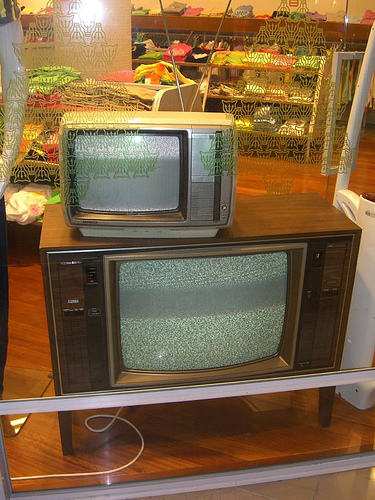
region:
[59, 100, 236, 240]
Small tan box tv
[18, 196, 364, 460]
Large older brown tv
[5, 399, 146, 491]
White cord on the ground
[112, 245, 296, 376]
Grey and white screen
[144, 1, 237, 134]
Silver antenna on tv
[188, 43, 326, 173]
Brown shelf with toys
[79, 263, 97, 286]
Black control panel on tv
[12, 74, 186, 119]
Clothes on top of shelf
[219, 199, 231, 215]
Silver power button on tv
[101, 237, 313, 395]
Brown trim of tv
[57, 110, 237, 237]
A silver television on top of larger tv.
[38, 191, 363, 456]
A brown television sitting on floor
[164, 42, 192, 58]
A pink tee shirt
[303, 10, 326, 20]
A purple shirt on shelf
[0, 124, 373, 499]
A wooden floor in clothing store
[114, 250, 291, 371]
A large television screen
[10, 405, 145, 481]
A white cord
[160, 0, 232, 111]
metal rabbit ear antena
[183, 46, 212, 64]
A black tee shirt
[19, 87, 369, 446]
two old television sets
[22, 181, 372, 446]
a television set encased in wood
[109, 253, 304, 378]
there is static on the screen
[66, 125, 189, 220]
this screen has static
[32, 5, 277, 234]
this tv has an antenna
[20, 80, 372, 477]
the televisions are in a store display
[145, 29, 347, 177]
a rack of tee shirts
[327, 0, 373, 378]
a store security detector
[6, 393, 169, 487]
the white power cord to a tv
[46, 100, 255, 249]
this TV is grey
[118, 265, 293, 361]
a television screen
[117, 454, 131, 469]
a white cord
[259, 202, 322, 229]
the top of the television is brown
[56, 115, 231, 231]
a television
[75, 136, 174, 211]
a television screen is grey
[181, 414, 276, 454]
the floor is wooden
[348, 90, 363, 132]
a pole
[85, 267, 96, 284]
buttons on the television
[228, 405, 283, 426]
a shadow on the floor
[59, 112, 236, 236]
tv on top of tv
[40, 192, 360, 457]
tv underneath silver tv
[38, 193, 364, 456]
large tv is brown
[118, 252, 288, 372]
snow on screen of tv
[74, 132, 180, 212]
snow on screen of tv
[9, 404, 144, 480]
white cord under tv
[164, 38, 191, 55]
folded pink shirt on shelf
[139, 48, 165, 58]
folded green shirt on shelf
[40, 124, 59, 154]
folded red shirt on shelf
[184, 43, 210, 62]
folded black shirt on shelf